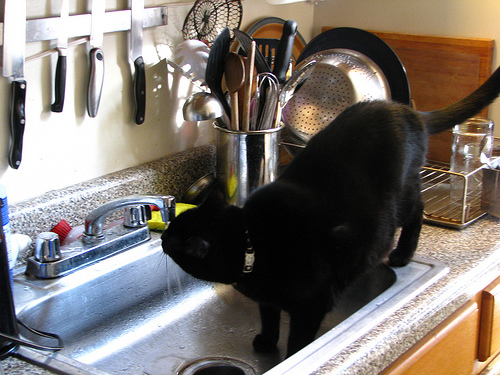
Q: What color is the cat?
A: Black.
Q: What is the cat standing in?
A: A sink.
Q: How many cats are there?
A: One.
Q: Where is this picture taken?
A: In a kitchen.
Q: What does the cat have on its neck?
A: A collar.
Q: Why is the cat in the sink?
A: It is drinking water from the faucet.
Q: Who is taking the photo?
A: A man or woman.